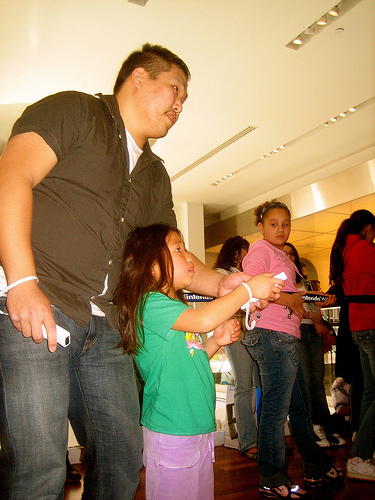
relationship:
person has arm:
[115, 221, 284, 495] [150, 280, 252, 332]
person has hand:
[115, 221, 284, 495] [213, 317, 241, 345]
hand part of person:
[205, 272, 291, 318] [4, 30, 163, 418]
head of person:
[254, 199, 292, 246] [240, 196, 341, 498]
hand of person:
[6, 271, 76, 350] [23, 49, 194, 393]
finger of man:
[42, 315, 61, 356] [0, 42, 268, 498]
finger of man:
[30, 320, 45, 347] [0, 42, 268, 498]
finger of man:
[21, 318, 33, 341] [0, 42, 268, 498]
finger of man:
[10, 319, 22, 331] [0, 42, 268, 498]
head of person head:
[252, 199, 292, 246] [119, 224, 199, 305]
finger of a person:
[232, 337, 240, 342] [115, 221, 284, 495]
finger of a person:
[267, 292, 276, 296] [115, 221, 284, 495]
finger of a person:
[271, 287, 280, 292] [115, 221, 284, 495]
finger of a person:
[272, 277, 280, 285] [115, 221, 284, 495]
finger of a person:
[232, 323, 241, 332] [115, 221, 284, 495]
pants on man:
[0, 295, 142, 498] [0, 42, 268, 498]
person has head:
[240, 198, 307, 499] [252, 196, 292, 247]